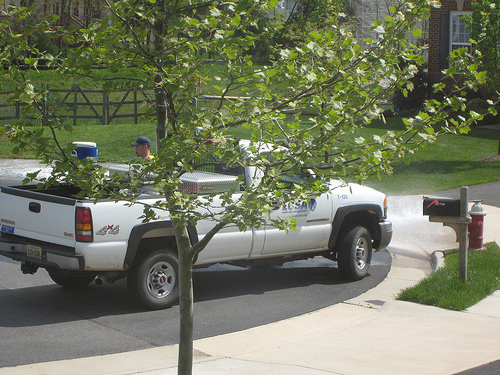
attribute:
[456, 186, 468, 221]
top — white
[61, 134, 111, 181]
cooler — blue, drink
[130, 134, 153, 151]
cap — baseball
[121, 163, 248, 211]
toolbox — large, metal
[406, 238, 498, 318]
patch — grass, small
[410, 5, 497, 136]
house — brick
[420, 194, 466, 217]
mailbox — black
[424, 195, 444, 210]
flag — red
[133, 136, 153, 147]
cap — blue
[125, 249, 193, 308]
tire — black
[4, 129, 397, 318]
truck — white, pick-up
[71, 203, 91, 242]
light — tail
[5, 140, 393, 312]
truck — white, pick-up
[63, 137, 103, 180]
cooler — blue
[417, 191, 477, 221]
mailbox — black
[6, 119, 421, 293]
truck — white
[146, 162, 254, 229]
box — silver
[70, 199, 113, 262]
light — red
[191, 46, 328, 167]
leaves — green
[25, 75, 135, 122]
fence — wood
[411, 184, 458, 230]
mailbox — black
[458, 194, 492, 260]
mailbox — red, white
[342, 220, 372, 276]
truck tire — black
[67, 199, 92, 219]
tail light — red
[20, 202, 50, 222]
handle — black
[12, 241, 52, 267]
license plate — white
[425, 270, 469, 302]
grass — green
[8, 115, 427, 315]
truck — white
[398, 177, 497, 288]
mailbox — black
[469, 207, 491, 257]
fire hydrant — red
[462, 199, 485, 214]
top — silver 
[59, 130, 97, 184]
water cooler — blue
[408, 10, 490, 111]
house — a brick house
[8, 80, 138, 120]
fence — a wooden fence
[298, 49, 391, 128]
leaves — green